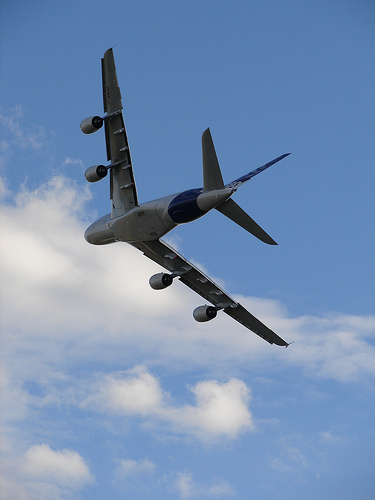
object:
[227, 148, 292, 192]
blue tail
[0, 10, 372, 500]
sky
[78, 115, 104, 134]
turbine engine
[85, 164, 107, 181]
turbine engine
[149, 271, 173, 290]
turbine engine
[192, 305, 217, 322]
turbine engine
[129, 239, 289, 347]
wing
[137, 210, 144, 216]
opening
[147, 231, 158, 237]
opening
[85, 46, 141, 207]
left wing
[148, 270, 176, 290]
engine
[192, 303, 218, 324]
engine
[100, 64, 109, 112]
writing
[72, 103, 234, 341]
propellers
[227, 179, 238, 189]
writing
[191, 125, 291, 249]
tail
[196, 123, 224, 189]
wing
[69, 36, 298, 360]
airplane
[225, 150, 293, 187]
wing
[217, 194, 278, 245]
wing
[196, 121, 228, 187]
wing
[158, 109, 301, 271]
small wings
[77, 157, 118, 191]
propeller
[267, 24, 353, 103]
skateboarder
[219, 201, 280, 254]
right wing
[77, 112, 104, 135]
engine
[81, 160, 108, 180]
engine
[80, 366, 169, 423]
cloud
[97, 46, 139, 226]
wing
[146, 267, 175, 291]
propeller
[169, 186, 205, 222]
stripe